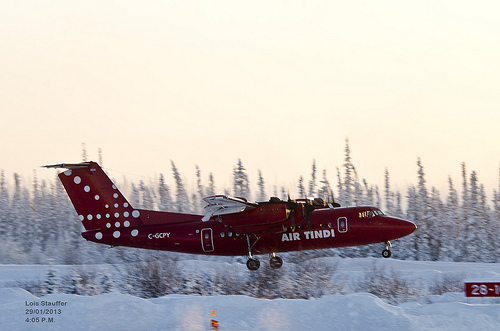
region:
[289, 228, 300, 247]
WORD AIR IS WRITTEN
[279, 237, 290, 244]
WORD AIR IS WRITTEN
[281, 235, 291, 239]
WORD AIR IS WRITTEN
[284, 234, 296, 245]
WORD AIR IS WRITTEN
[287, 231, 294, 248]
WORD AIR IS WRITTEN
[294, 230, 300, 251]
WORD AIR IS WRITTEN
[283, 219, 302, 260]
WORD AIR IS WRITTEN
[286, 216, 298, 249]
WORD AIR IS WRITTEN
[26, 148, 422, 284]
A plane flies through the air.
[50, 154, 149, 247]
Spots on the tail.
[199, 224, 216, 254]
The door of the plane.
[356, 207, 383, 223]
The pilot in the cockpit.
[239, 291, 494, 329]
Snow piled on the bank.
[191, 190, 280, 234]
The wing of the plane.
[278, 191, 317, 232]
The propellers of the plane.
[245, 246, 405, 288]
The wheels for landing.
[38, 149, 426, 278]
The plane landing.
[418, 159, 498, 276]
Snoiw covered trees in forrest.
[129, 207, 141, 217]
white dots on airplane tail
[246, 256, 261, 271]
black wheels under red airplane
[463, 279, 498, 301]
red sign in snow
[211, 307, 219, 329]
orange light under airplane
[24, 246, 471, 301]
snow covered bushes behind airplane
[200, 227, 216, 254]
door on airplane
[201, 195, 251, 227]
wing of airplane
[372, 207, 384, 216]
windshield on airplane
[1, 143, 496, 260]
forest of trees behind airplane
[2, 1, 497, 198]
pink sky above airplane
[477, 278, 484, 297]
number 28 is written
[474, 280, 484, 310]
number 28 is written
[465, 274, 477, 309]
number 28 is written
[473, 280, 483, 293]
number 28 is written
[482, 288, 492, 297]
number 28 is written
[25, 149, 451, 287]
a red airplane in the air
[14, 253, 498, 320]
snow on the ground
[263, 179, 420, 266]
propellers on an airplane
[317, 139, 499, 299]
trees covered with snow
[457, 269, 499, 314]
sign on the ground at an airport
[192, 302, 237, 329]
flag on the ground at an airport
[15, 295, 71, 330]
photographer information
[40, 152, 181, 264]
tail of a red airplane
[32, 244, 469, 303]
bushes on the ground covered in snow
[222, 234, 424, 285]
landing gear on an airplane